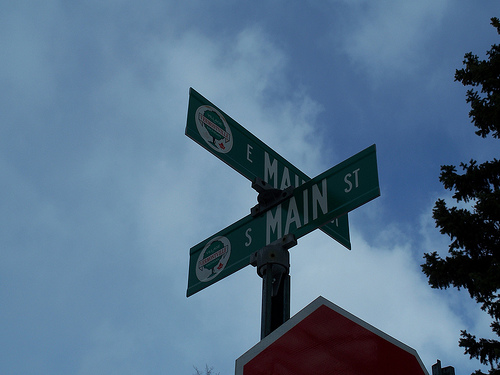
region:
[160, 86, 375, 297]
2 perpendicular street signs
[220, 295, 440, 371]
partial view of stop sign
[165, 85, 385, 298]
2 green street signs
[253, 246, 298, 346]
black iron pole supports signs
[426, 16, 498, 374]
partial view of green tree on right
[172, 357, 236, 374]
partial view of another tree next to stop sign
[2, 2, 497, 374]
photo appears to have been taken early evening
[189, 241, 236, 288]
white circular logo on street sign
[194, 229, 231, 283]
green tree inside white circle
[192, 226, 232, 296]
red letters on white and green logo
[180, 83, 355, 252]
E Main St sign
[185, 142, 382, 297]
S Main St sign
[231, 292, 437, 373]
Top of a stop sign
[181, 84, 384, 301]
Two street signs atop a pole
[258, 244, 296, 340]
Metal pole holding street signs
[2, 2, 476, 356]
Clouds in blue sky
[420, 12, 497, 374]
Green, leafy tree branches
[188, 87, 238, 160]
Symbol of a tree on E Main sign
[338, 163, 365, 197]
The letters ST on street sign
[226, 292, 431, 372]
White border around stop sign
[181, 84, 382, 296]
green and white street sign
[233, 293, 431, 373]
top of a stop sign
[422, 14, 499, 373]
tall tree next to sign post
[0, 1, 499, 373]
blue and white overcast sky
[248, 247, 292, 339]
metal pole behind signs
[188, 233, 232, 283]
tree picture on sign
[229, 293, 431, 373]
red and white stop sign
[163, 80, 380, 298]
rectangular street signs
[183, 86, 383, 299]
two green cross street signs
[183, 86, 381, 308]
two green street signs on a pole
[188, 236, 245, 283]
round tree graphic design on a street sign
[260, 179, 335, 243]
white text on a green street sign reading Main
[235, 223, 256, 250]
white text on a green street sign reading S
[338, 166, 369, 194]
text on a street sign reading ST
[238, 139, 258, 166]
white text on a street sign reading E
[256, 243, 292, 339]
street pole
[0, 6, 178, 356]
clouds in a blue sky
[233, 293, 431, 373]
the top of a red sign on a pole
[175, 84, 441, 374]
Street sign depicting Main Street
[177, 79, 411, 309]
Green street sign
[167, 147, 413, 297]
South Main Street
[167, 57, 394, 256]
East Main Street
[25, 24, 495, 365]
Clouds behind the street sign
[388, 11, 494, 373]
Tree near the street sign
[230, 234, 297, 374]
Pole that holds the street sign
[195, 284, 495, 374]
A sign below the street sign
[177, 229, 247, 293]
A tree on the street sign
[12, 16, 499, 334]
Blue sky in the background